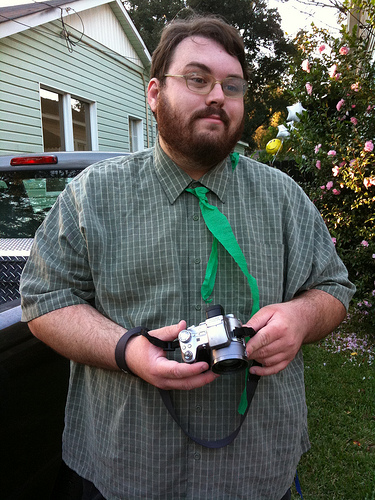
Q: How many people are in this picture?
A: One.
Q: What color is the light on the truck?
A: Red.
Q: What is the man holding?
A: A camera.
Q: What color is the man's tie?
A: Green.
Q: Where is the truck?
A: Behind the man.